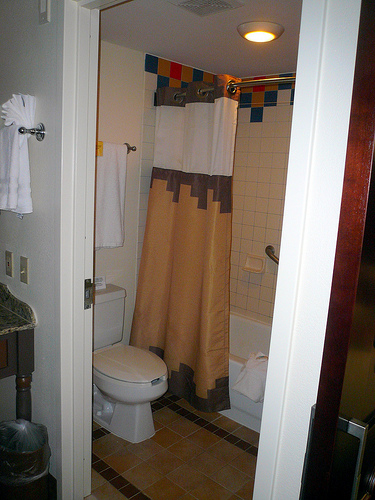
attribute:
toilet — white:
[86, 275, 176, 431]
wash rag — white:
[235, 349, 270, 404]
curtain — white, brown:
[116, 118, 259, 369]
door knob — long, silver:
[346, 415, 371, 498]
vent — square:
[172, 2, 241, 17]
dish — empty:
[243, 253, 265, 276]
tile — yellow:
[262, 91, 279, 107]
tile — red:
[249, 108, 264, 123]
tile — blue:
[249, 91, 266, 106]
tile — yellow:
[237, 91, 250, 107]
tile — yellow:
[248, 76, 265, 93]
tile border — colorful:
[143, 51, 219, 86]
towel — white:
[108, 198, 120, 240]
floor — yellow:
[132, 450, 245, 498]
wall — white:
[18, 64, 99, 397]